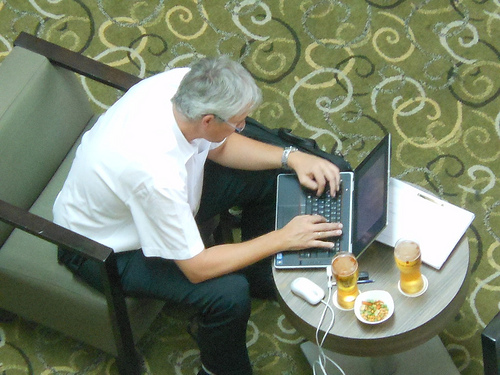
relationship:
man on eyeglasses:
[51, 52, 345, 373] [215, 107, 250, 127]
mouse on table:
[288, 268, 329, 308] [262, 165, 476, 345]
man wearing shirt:
[51, 52, 345, 373] [50, 62, 229, 264]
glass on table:
[391, 235, 425, 295] [263, 172, 483, 374]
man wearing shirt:
[51, 52, 345, 373] [14, 82, 215, 239]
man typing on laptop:
[51, 52, 345, 373] [275, 133, 396, 281]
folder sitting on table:
[372, 175, 474, 271] [270, 178, 470, 372]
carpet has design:
[0, 3, 495, 371] [4, 1, 495, 373]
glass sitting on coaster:
[391, 235, 425, 295] [397, 275, 430, 298]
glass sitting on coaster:
[331, 253, 365, 307] [331, 287, 361, 311]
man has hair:
[51, 52, 345, 373] [170, 48, 265, 125]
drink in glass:
[395, 252, 425, 294] [390, 239, 430, 297]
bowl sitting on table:
[357, 290, 394, 325] [262, 165, 476, 345]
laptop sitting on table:
[271, 129, 395, 272] [263, 172, 483, 374]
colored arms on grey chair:
[0, 200, 145, 367] [0, 45, 135, 369]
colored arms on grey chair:
[11, 27, 135, 100] [0, 45, 135, 369]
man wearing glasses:
[51, 52, 345, 373] [194, 102, 250, 136]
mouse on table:
[288, 273, 328, 307] [262, 176, 477, 352]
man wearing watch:
[51, 52, 345, 373] [269, 139, 305, 171]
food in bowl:
[360, 300, 388, 320] [350, 288, 396, 326]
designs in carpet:
[347, 60, 459, 142] [0, 3, 495, 371]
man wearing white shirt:
[51, 52, 345, 373] [48, 67, 227, 262]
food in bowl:
[360, 300, 388, 320] [350, 284, 397, 324]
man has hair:
[51, 52, 345, 373] [177, 46, 267, 126]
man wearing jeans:
[51, 52, 345, 373] [55, 157, 287, 372]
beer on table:
[385, 234, 442, 298] [270, 178, 470, 372]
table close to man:
[270, 178, 470, 372] [51, 52, 345, 373]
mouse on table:
[288, 273, 328, 307] [274, 180, 472, 344]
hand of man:
[291, 152, 348, 193] [51, 52, 345, 373]